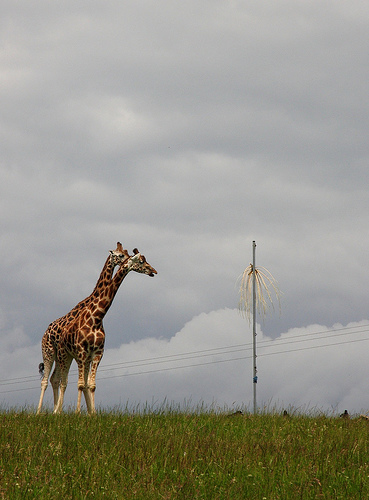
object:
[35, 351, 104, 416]
legs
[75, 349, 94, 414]
leg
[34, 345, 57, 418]
leg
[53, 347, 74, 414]
leg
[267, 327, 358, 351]
electric lines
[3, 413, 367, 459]
grass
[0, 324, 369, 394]
electric lines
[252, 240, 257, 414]
metal pole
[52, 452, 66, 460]
seeds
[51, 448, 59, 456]
stem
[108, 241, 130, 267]
head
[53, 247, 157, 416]
giraffe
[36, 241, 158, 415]
body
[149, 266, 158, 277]
mouth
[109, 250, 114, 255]
ear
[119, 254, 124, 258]
eye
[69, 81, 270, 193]
sky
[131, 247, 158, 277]
head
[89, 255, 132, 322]
neck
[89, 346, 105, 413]
leg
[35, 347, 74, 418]
leg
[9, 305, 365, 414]
clouds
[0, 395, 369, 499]
grass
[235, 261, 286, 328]
hay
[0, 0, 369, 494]
scene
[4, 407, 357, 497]
field